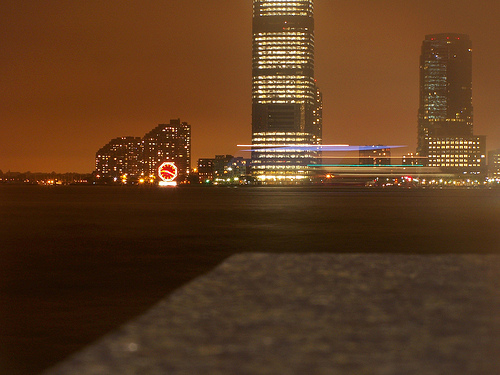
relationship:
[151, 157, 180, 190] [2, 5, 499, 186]
clock in city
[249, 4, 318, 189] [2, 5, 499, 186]
building in city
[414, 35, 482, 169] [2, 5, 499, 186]
building in city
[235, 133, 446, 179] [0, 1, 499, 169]
light streaks in sky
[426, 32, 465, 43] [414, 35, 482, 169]
lights on he top of building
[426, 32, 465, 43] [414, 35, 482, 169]
lights on building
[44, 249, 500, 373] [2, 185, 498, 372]
slab next to water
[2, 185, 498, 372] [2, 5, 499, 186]
water in front of city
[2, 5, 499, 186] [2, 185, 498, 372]
city beside water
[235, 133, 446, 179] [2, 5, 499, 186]
light streaks in city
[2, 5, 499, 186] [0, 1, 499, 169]
city with sky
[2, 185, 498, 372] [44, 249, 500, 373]
water beside slab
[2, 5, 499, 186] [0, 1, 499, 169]
city under sky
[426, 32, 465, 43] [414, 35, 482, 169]
lights on top of building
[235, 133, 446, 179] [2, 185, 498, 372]
light streaks behind water